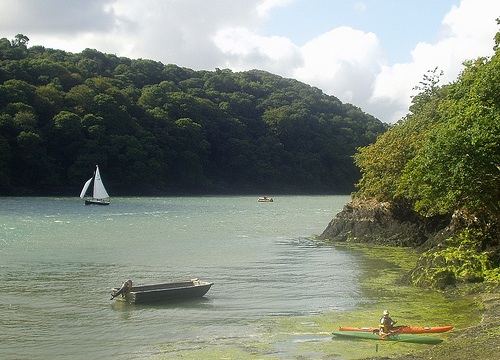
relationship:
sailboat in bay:
[79, 163, 110, 209] [2, 196, 477, 358]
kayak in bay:
[335, 323, 453, 345] [2, 196, 477, 358]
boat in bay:
[108, 276, 216, 303] [2, 196, 477, 358]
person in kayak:
[380, 308, 398, 339] [335, 323, 453, 345]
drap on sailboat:
[92, 164, 113, 203] [79, 163, 110, 209]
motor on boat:
[108, 277, 131, 302] [108, 276, 216, 303]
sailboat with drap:
[79, 163, 110, 209] [92, 164, 113, 203]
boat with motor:
[108, 276, 216, 303] [108, 277, 131, 302]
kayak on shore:
[335, 323, 453, 345] [375, 278, 499, 360]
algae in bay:
[364, 246, 471, 325] [2, 196, 477, 358]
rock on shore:
[411, 222, 498, 301] [375, 278, 499, 360]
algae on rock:
[364, 246, 471, 325] [411, 222, 498, 301]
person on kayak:
[380, 308, 398, 339] [335, 323, 453, 345]